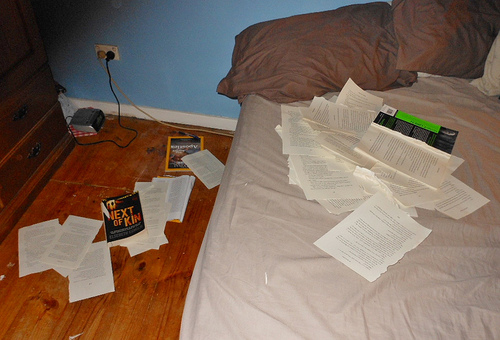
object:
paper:
[309, 190, 436, 283]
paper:
[356, 124, 466, 191]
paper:
[286, 150, 367, 202]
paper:
[422, 168, 491, 221]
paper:
[334, 77, 384, 113]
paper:
[312, 197, 434, 283]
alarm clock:
[70, 107, 106, 132]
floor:
[131, 277, 174, 308]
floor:
[51, 148, 106, 194]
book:
[102, 190, 145, 247]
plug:
[93, 50, 117, 60]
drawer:
[0, 65, 67, 164]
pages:
[16, 134, 226, 302]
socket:
[91, 41, 121, 62]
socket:
[88, 44, 126, 66]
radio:
[66, 106, 106, 137]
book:
[276, 76, 484, 285]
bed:
[177, 0, 499, 339]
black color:
[117, 202, 131, 208]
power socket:
[87, 40, 127, 63]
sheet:
[176, 71, 499, 338]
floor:
[0, 298, 80, 335]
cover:
[215, 0, 500, 107]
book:
[163, 136, 204, 173]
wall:
[33, 0, 391, 131]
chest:
[0, 2, 76, 245]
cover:
[101, 187, 146, 245]